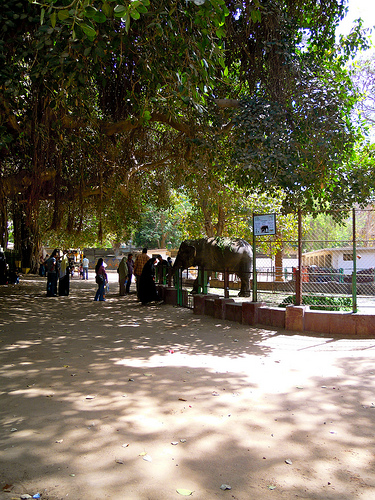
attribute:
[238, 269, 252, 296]
legs — back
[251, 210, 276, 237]
sign — white, visitor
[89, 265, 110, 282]
shirt — purple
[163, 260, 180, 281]
trunk — long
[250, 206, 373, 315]
fence — tall, chain, link, metal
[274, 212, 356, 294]
fence — tall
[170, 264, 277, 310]
fence — short, green, metal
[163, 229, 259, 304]
elephant — large, grey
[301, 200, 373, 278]
building — white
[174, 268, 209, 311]
gate — green, metal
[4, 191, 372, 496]
area — gated